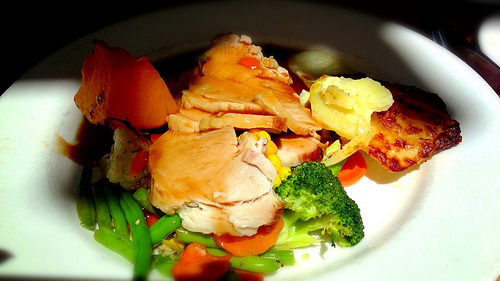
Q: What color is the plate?
A: White.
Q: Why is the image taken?
A: Remembrance.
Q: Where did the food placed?
A: On white plate.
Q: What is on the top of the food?
A: Turkey.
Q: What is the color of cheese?
A: Yellow.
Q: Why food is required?
A: Energy.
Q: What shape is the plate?
A: Circular.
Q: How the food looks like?
A: Fresh.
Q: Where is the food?
A: On a plate.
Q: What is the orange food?
A: Carrots.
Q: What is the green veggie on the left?
A: String beans.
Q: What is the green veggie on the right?
A: Broccoli.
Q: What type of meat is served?
A: Chicken.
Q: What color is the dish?
A: White.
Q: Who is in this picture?
A: No one.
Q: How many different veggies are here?
A: Three.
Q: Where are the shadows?
A: On the plate.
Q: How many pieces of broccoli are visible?
A: One.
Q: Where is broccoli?
A: On the plate.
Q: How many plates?
A: 1.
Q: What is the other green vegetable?
A: Green beans.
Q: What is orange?
A: Carrots.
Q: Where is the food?
A: On a plate.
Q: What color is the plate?
A: White.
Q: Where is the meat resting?
A: On top of vegetables.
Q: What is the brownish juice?
A: Gravy.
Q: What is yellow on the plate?
A: Corn.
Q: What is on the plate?
A: Food.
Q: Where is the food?
A: On the plate.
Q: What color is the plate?
A: White.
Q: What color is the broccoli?
A: Green.